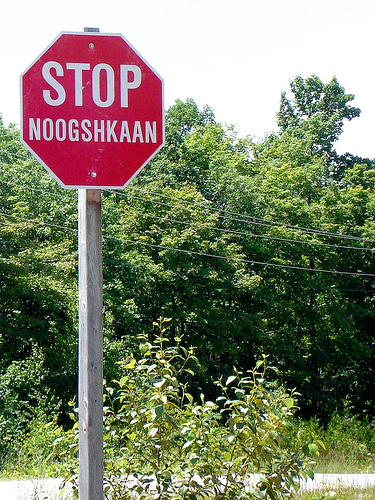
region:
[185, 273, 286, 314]
Leaves are green color.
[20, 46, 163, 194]
One sign board is on the road side.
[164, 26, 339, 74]
Sky is white color.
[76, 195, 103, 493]
Pole is gray color.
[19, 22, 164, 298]
Board is attached to the pole.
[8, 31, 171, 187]
Board is red and white color.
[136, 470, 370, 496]
Road is grey color.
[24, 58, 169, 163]
Letters are white color.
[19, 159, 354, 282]
Wire lines are passing across the road.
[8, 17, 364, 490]
Day time picture.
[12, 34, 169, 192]
The stop sign mounted on the wooden pole.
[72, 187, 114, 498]
The wooden pole the stop sign is mounted on.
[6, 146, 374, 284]
The wires behind the stop sign.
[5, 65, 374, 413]
The trees behind the stop sign.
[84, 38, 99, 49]
The top screw on the stop sign.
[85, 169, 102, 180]
The bottom screw on the stop sign.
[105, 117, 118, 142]
The letter K on the stop sign.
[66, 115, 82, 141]
The letter G on the stop sign.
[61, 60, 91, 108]
The letter T on the stop sign.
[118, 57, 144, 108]
The letter P on the stop sign.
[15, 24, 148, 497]
stop sign op wood pole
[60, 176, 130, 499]
wood pole of stop sign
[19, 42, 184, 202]
red and white sign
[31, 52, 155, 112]
white letters on red sign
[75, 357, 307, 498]
greenery by sign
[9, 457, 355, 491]
road behind stop sign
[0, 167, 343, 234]
wires hanging over road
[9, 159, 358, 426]
trees behind road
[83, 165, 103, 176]
metal screw at bottom of sign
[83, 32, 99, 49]
metal screw on top of sign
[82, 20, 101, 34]
The tip of the wooden pole the stop sign is mounted on.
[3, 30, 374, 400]
The trees in the background.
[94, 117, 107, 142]
The letter H on the stop sign.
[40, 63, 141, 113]
The word 'Stop' on traffic sign.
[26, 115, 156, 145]
The word 'Noogshkaan' on traffic sign.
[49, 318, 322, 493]
Green bush growing next to traffic sign.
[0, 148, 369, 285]
Electric wires above traffic sign.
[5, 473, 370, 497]
Roadway along the forest.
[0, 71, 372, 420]
Thick green trees in forest.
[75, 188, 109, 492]
Wood pole supporting traffic sign.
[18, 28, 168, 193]
Stop sign showing English and foreign language.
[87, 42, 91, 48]
Bolt afixing traffic sign to pole.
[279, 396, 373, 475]
Weeds growing along the roadway.